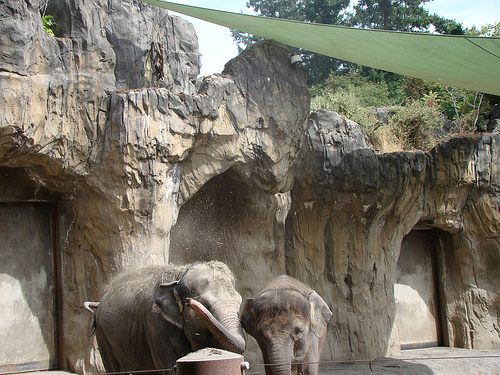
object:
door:
[393, 226, 444, 350]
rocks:
[142, 105, 183, 138]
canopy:
[136, 0, 500, 98]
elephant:
[83, 260, 248, 374]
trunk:
[183, 297, 248, 355]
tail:
[83, 302, 101, 316]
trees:
[340, 0, 463, 37]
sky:
[445, 2, 482, 16]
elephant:
[240, 274, 334, 375]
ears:
[307, 290, 333, 338]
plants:
[360, 105, 422, 155]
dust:
[165, 275, 194, 304]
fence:
[86, 346, 500, 374]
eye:
[291, 325, 304, 338]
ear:
[151, 279, 184, 330]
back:
[96, 261, 191, 302]